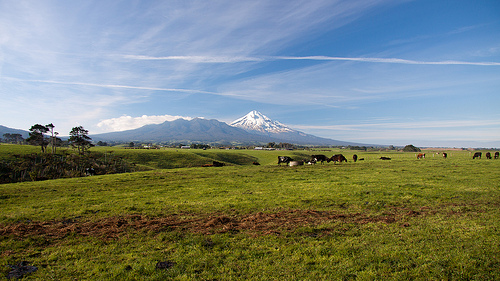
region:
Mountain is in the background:
[88, 98, 368, 153]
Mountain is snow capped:
[218, 104, 293, 144]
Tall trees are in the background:
[13, 113, 98, 167]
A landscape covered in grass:
[1, 149, 498, 279]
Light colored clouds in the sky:
[3, 4, 498, 112]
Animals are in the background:
[271, 140, 497, 177]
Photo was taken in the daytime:
[2, 3, 498, 275]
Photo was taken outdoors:
[5, 6, 497, 273]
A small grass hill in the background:
[0, 135, 177, 182]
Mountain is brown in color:
[141, 115, 236, 143]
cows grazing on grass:
[270, 146, 362, 173]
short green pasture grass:
[186, 174, 279, 208]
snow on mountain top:
[233, 102, 286, 137]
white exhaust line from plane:
[290, 45, 395, 70]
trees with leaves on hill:
[23, 111, 100, 157]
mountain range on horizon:
[130, 114, 240, 150]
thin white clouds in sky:
[124, 9, 239, 46]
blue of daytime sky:
[362, 7, 432, 51]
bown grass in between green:
[143, 205, 288, 251]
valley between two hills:
[0, 162, 140, 189]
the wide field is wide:
[138, 142, 376, 266]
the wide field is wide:
[151, 164, 295, 269]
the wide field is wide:
[215, 211, 343, 275]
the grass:
[230, 188, 308, 275]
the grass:
[290, 189, 327, 278]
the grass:
[258, 162, 300, 264]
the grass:
[266, 188, 323, 264]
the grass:
[279, 154, 349, 271]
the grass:
[294, 231, 336, 276]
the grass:
[289, 233, 313, 275]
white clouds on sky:
[101, 40, 253, 131]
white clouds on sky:
[81, 24, 181, 108]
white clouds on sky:
[95, 77, 152, 105]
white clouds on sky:
[105, 27, 165, 91]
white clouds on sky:
[111, 61, 176, 128]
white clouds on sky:
[105, 65, 170, 93]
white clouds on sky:
[121, 41, 169, 106]